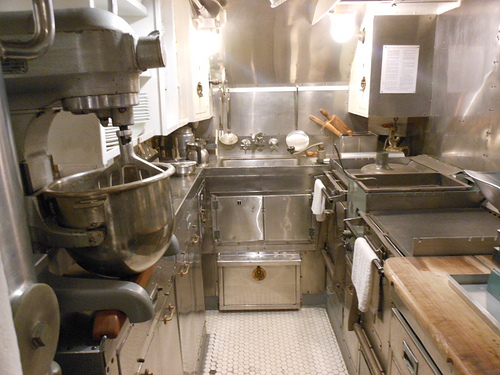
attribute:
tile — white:
[209, 332, 215, 337]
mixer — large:
[2, 5, 176, 340]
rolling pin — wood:
[308, 110, 345, 141]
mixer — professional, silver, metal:
[5, 0, 182, 272]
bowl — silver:
[37, 152, 184, 282]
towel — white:
[312, 236, 414, 340]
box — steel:
[213, 248, 303, 312]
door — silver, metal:
[210, 177, 260, 278]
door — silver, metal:
[261, 179, 318, 252]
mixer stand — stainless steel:
[0, 5, 169, 126]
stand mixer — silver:
[0, 5, 185, 320]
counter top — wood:
[384, 255, 496, 374]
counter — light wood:
[383, 250, 497, 374]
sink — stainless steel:
[218, 133, 307, 195]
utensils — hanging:
[213, 84, 226, 134]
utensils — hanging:
[222, 86, 235, 131]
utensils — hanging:
[291, 84, 303, 128]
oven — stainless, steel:
[318, 169, 343, 274]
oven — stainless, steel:
[334, 219, 391, 360]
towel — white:
[350, 235, 382, 315]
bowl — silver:
[334, 122, 449, 214]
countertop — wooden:
[386, 254, 498, 369]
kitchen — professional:
[1, 0, 498, 375]